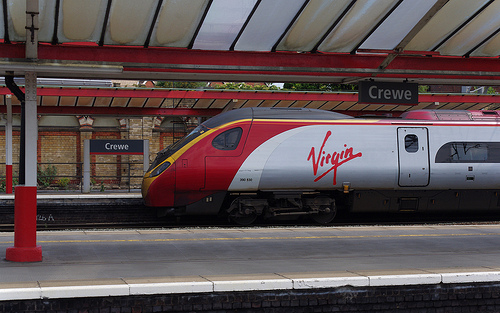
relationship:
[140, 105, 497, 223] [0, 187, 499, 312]
train on platform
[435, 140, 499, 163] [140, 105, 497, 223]
window on train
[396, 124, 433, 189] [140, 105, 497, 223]
door on train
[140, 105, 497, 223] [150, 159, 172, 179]
train has headlight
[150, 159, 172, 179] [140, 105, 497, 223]
headlight on train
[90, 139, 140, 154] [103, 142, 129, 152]
sign says crewe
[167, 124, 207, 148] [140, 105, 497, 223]
windshield on train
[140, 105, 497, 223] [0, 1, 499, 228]
train in subway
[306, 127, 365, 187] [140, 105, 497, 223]
logo on train